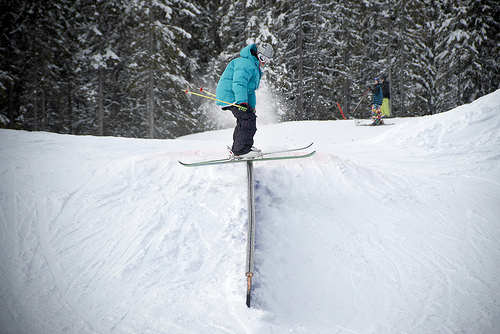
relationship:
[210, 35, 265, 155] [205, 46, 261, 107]
person wearing jacket